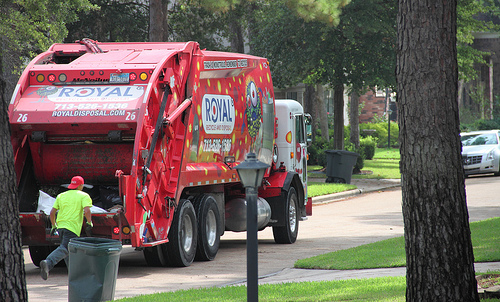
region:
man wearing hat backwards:
[35, 171, 95, 243]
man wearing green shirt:
[49, 170, 96, 233]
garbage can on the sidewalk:
[63, 237, 125, 300]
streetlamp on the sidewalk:
[230, 149, 266, 300]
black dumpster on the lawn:
[320, 143, 364, 193]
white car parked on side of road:
[459, 120, 498, 171]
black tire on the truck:
[277, 183, 301, 245]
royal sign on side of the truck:
[199, 89, 237, 139]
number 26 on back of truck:
[13, 108, 27, 127]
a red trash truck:
[3, 35, 318, 280]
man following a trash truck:
[33, 169, 103, 281]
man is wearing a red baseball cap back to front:
[38, 170, 95, 283]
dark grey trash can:
[59, 231, 125, 300]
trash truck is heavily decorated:
[3, 31, 315, 263]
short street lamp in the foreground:
[234, 143, 274, 300]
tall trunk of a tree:
[388, 3, 486, 300]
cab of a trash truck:
[271, 93, 315, 203]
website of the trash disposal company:
[46, 105, 129, 118]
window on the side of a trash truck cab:
[293, 112, 307, 145]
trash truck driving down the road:
[6, 41, 310, 263]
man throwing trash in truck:
[41, 173, 95, 281]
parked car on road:
[460, 131, 499, 173]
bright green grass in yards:
[111, 222, 497, 299]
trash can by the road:
[68, 236, 117, 298]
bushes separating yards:
[309, 125, 376, 163]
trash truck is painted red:
[8, 39, 312, 260]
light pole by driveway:
[236, 149, 272, 299]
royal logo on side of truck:
[201, 94, 234, 134]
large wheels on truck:
[171, 189, 299, 261]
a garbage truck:
[9, 29, 330, 250]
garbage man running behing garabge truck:
[39, 168, 111, 276]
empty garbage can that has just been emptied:
[54, 226, 144, 293]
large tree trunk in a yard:
[377, 5, 489, 295]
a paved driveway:
[277, 255, 497, 284]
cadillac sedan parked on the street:
[454, 120, 499, 172]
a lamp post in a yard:
[227, 159, 285, 296]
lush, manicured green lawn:
[335, 250, 392, 265]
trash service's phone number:
[50, 98, 130, 113]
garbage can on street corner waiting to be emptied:
[317, 141, 366, 184]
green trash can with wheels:
[321, 144, 361, 187]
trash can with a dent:
[63, 230, 130, 300]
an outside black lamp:
[235, 147, 268, 299]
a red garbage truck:
[6, 34, 317, 271]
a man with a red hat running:
[37, 171, 99, 285]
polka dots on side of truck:
[178, 44, 280, 194]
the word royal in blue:
[202, 93, 242, 127]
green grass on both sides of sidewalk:
[188, 242, 498, 300]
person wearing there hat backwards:
[60, 172, 88, 194]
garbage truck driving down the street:
[7, 21, 487, 283]